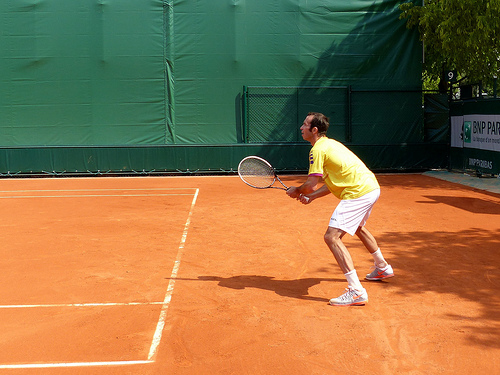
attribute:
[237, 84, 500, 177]
fence — painted, green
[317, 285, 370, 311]
shoe — orange, white, multi colored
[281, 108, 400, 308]
man — playing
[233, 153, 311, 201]
racket — tennis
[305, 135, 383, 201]
shirt — yellow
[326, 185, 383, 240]
shorts — white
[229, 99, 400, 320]
player — waiting, male, crouching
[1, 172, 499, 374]
floor — orange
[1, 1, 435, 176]
covering — green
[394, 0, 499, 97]
trees — shading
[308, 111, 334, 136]
hair — brown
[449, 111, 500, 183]
signs — hanging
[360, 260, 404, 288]
sneaker — nike, white, orange